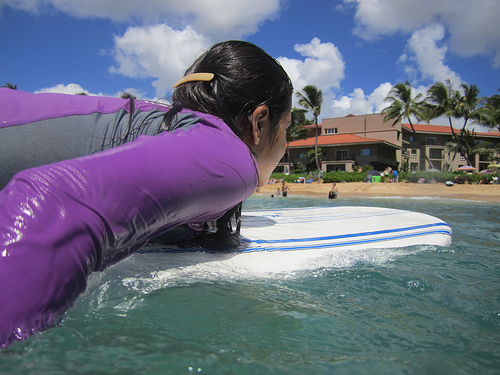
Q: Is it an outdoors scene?
A: Yes, it is outdoors.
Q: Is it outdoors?
A: Yes, it is outdoors.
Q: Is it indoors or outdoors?
A: It is outdoors.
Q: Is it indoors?
A: No, it is outdoors.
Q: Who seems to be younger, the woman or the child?
A: The child is younger than the woman.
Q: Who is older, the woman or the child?
A: The woman is older than the child.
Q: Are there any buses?
A: No, there are no buses.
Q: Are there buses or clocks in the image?
A: No, there are no buses or clocks.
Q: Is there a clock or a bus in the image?
A: No, there are no buses or clocks.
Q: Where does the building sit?
A: The building sits on the beach.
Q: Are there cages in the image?
A: No, there are no cages.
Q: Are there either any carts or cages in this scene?
A: No, there are no cages or carts.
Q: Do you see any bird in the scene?
A: No, there are no birds.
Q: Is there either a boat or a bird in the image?
A: No, there are no birds or boats.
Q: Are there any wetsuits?
A: Yes, there is a wetsuit.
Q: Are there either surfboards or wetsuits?
A: Yes, there is a wetsuit.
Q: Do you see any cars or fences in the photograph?
A: No, there are no cars or fences.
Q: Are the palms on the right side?
A: Yes, the palms are on the right of the image.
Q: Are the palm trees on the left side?
A: No, the palm trees are on the right of the image.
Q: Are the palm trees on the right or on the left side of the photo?
A: The palm trees are on the right of the image.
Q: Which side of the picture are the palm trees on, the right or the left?
A: The palm trees are on the right of the image.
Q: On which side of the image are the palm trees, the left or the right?
A: The palm trees are on the right of the image.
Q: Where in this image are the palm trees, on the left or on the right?
A: The palm trees are on the right of the image.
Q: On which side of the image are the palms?
A: The palms are on the right of the image.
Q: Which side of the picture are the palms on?
A: The palms are on the right of the image.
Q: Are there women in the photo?
A: Yes, there is a woman.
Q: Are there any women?
A: Yes, there is a woman.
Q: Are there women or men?
A: Yes, there is a woman.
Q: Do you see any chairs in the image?
A: No, there are no chairs.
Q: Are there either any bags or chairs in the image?
A: No, there are no chairs or bags.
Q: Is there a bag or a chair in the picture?
A: No, there are no chairs or bags.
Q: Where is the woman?
A: The woman is in the water.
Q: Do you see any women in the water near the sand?
A: Yes, there is a woman in the water.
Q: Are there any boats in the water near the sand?
A: No, there is a woman in the water.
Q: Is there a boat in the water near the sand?
A: No, there is a woman in the water.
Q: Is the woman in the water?
A: Yes, the woman is in the water.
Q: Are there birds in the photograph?
A: No, there are no birds.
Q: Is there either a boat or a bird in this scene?
A: No, there are no birds or boats.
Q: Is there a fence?
A: No, there are no fences.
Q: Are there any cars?
A: No, there are no cars.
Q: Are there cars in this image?
A: No, there are no cars.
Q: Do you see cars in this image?
A: No, there are no cars.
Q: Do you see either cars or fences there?
A: No, there are no cars or fences.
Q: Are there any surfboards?
A: Yes, there is a surfboard.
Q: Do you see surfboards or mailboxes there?
A: Yes, there is a surfboard.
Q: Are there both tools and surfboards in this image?
A: No, there is a surfboard but no tools.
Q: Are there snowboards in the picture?
A: No, there are no snowboards.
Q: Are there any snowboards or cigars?
A: No, there are no snowboards or cigars.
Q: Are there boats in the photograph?
A: No, there are no boats.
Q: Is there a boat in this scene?
A: No, there are no boats.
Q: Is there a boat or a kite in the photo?
A: No, there are no boats or kites.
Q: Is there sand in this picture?
A: Yes, there is sand.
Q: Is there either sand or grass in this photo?
A: Yes, there is sand.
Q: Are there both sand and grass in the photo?
A: No, there is sand but no grass.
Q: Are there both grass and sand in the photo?
A: No, there is sand but no grass.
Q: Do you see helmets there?
A: No, there are no helmets.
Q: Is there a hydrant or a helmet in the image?
A: No, there are no helmets or fire hydrants.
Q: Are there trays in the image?
A: No, there are no trays.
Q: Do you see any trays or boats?
A: No, there are no trays or boats.